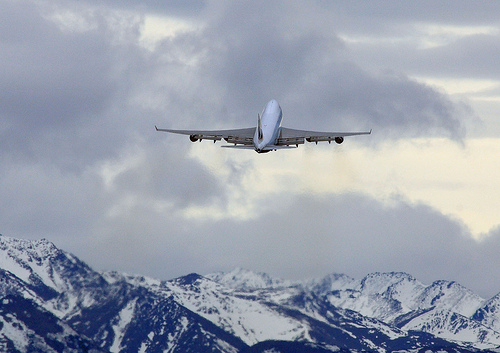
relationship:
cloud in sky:
[0, 5, 498, 283] [2, 0, 485, 300]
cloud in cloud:
[0, 5, 498, 283] [0, 5, 498, 283]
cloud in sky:
[0, 5, 498, 283] [85, 88, 430, 292]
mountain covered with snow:
[0, 237, 498, 349] [0, 235, 499, 351]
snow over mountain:
[0, 235, 499, 351] [41, 245, 471, 340]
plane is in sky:
[152, 100, 373, 158] [2, 3, 499, 275]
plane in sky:
[98, 85, 335, 187] [33, 13, 486, 278]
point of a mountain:
[232, 261, 248, 272] [163, 251, 391, 351]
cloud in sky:
[0, 5, 498, 283] [31, 29, 213, 141]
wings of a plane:
[150, 125, 372, 144] [153, 96, 373, 153]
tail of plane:
[254, 113, 267, 146] [152, 84, 374, 160]